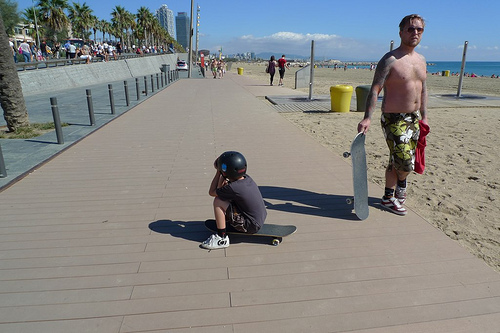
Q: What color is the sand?
A: Brown.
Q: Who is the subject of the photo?
A: The people.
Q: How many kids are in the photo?
A: One.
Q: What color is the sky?
A: Blue.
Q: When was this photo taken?
A: During the day.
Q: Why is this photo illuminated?
A: Sunlight.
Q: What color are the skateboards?
A: Black.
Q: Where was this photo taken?
A: At the beach.